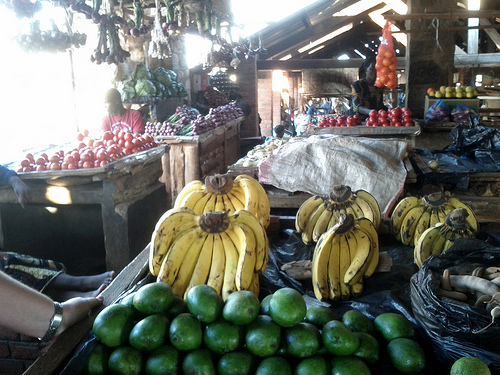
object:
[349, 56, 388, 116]
buyer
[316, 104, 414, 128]
goods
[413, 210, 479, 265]
bananas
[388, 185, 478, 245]
bananas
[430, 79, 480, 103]
apples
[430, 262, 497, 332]
items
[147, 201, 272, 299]
bananas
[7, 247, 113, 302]
legs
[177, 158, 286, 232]
banana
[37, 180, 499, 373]
cart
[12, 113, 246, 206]
crate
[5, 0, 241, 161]
food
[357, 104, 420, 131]
apples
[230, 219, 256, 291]
banana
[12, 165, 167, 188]
bin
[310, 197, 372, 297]
bananas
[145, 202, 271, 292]
bunch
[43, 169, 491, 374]
fruit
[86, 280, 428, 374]
avocados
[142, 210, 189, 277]
banana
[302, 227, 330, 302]
banana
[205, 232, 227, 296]
banana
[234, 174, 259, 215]
banana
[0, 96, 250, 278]
cart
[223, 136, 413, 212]
cart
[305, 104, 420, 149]
cart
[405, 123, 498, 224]
cart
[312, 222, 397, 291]
bunch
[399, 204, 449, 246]
bunch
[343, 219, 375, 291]
bananas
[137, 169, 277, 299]
bananas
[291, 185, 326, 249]
bananas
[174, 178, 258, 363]
fruit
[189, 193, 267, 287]
banana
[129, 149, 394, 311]
cart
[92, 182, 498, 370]
produce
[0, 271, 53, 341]
arm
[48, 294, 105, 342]
hand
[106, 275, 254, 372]
fruit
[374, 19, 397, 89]
bag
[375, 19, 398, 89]
oranges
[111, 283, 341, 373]
limes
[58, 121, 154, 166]
apples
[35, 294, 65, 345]
watch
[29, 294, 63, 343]
wrist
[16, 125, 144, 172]
tomatoes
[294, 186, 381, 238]
bananas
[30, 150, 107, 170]
apples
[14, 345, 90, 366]
shelf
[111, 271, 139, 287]
shelf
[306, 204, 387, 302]
bunch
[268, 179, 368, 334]
cart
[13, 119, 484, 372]
wares